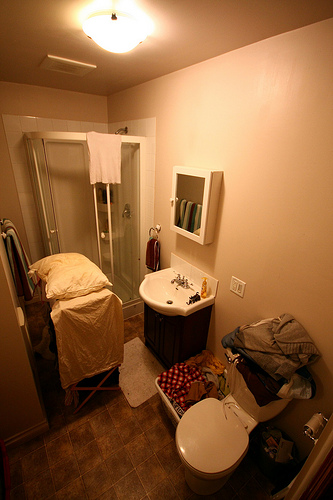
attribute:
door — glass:
[42, 138, 142, 304]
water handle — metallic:
[123, 206, 131, 220]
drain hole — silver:
[166, 299, 174, 304]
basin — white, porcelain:
[139, 267, 210, 316]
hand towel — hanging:
[145, 239, 159, 269]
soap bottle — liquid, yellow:
[200, 277, 208, 297]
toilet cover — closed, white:
[177, 397, 251, 474]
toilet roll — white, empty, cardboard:
[304, 413, 325, 432]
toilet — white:
[175, 347, 310, 495]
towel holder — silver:
[148, 223, 162, 239]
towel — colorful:
[4, 222, 34, 300]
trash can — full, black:
[259, 430, 298, 482]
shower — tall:
[23, 130, 143, 300]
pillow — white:
[32, 253, 112, 300]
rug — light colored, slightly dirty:
[120, 335, 163, 406]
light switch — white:
[228, 275, 245, 296]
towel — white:
[87, 131, 123, 184]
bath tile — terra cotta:
[3, 114, 155, 276]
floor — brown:
[2, 310, 275, 500]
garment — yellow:
[190, 351, 224, 373]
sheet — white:
[51, 291, 125, 387]